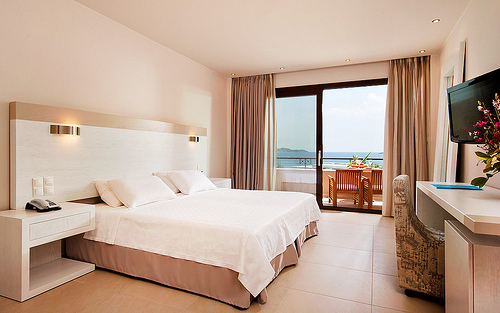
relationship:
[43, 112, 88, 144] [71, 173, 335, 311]
lights hanging over bed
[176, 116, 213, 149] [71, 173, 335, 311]
lights hanging over bed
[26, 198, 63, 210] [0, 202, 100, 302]
phone on nightstand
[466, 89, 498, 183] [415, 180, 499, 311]
flowers on desk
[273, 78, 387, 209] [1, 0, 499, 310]
patio outside hotel room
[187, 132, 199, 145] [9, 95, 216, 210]
light on headboard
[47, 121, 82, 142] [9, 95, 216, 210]
light on headboard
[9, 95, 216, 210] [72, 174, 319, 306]
headboard on bed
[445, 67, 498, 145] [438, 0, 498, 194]
television hanging on wall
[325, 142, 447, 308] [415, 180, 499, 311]
chair pushed up to desk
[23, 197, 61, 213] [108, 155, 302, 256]
phone beside bed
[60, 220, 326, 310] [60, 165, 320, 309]
sheets on bed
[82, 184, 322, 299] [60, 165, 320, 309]
sheets on bed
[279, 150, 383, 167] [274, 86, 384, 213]
ocean seen through window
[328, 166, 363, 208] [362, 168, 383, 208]
chair next to chair